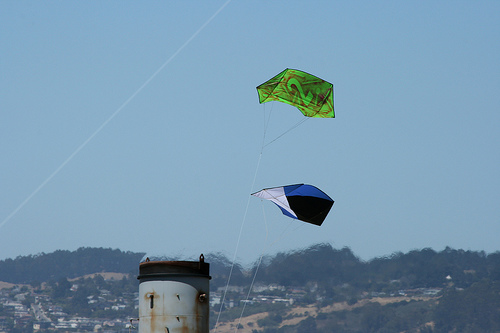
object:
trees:
[301, 243, 332, 286]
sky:
[47, 31, 216, 134]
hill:
[210, 293, 442, 331]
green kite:
[253, 65, 335, 121]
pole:
[138, 283, 224, 330]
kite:
[246, 183, 336, 228]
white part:
[249, 184, 300, 220]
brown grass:
[222, 307, 279, 331]